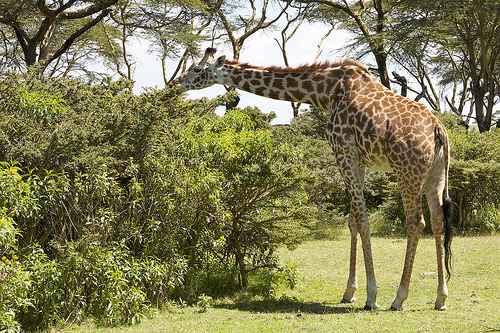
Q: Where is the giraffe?
A: The zoo.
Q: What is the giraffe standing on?
A: Grass.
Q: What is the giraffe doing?
A: Eating.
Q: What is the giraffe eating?
A: Leaves.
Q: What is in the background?
A: Tall trees.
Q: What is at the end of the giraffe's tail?
A: Black hair.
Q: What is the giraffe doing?
A: Eating.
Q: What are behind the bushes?
A: Trees.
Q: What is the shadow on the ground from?
A: The giraffe.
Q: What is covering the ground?
A: Grass.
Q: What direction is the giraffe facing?
A: The left.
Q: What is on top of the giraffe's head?
A: Ossicones.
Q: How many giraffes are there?
A: One.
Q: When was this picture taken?
A: Daytime.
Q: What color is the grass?
A: Green.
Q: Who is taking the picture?
A: Photographer.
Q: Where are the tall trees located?
A: Background.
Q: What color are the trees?
A: Green and brown.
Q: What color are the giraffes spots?
A: Brown.